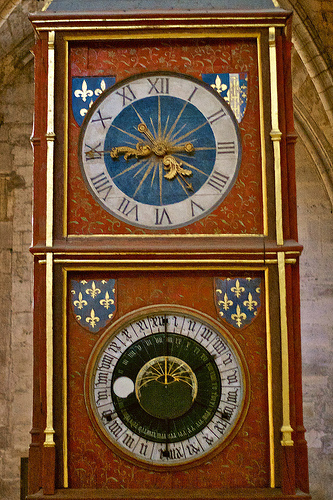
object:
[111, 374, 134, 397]
moon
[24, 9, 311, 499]
wooden case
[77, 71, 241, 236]
clock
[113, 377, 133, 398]
circle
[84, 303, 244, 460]
face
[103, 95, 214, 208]
circle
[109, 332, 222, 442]
circle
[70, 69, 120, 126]
shield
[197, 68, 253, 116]
shield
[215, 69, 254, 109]
crest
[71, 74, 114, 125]
crest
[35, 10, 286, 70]
wood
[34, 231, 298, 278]
wood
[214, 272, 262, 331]
crest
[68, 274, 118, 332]
crest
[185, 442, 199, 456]
roman numeral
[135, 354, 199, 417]
picture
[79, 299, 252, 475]
clock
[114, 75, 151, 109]
roman numeral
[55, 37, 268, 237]
clock face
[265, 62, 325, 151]
wood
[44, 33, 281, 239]
trim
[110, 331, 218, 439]
black circle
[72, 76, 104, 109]
arms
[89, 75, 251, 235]
face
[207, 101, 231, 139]
numeral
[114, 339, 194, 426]
center